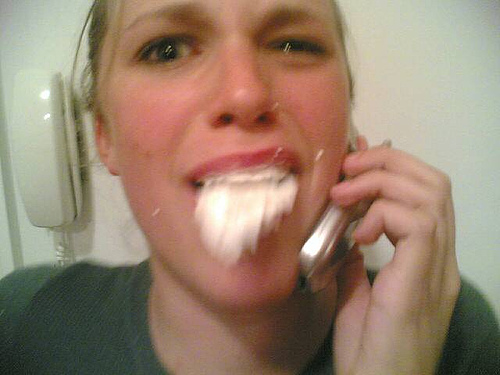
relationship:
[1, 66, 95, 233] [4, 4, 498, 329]
phone on wall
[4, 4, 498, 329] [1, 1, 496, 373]
wall behind woman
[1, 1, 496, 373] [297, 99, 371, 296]
woman holding cellphone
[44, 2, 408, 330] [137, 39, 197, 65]
woman has eye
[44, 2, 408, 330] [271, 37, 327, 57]
woman has eye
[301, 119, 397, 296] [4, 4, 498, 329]
phone hanging on wall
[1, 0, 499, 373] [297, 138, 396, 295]
girl holding silver phone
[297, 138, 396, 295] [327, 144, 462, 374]
silver phone in left hand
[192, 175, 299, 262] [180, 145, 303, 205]
foam coming out of womans mouth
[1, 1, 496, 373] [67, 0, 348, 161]
woman has hair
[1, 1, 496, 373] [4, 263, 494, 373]
woman wearing a shirt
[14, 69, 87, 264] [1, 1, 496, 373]
phone behind woman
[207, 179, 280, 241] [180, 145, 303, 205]
stuff in mouth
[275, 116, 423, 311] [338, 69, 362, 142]
cellphone held to ear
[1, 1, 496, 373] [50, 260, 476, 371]
woman wearing shirt